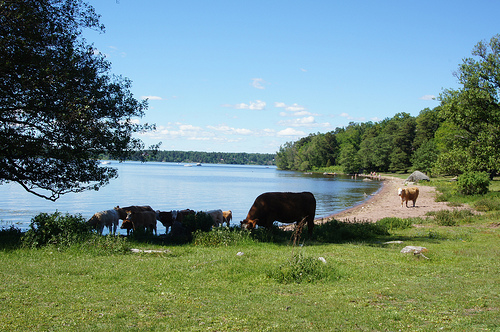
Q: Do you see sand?
A: Yes, there is sand.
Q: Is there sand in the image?
A: Yes, there is sand.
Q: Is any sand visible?
A: Yes, there is sand.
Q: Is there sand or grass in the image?
A: Yes, there is sand.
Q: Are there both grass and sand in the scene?
A: Yes, there are both sand and grass.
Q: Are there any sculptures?
A: No, there are no sculptures.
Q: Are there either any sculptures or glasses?
A: No, there are no sculptures or glasses.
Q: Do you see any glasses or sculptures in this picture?
A: No, there are no sculptures or glasses.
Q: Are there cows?
A: Yes, there is a cow.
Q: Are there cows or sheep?
A: Yes, there is a cow.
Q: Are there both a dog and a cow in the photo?
A: No, there is a cow but no dogs.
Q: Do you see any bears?
A: No, there are no bears.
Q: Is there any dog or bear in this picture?
A: No, there are no bears or dogs.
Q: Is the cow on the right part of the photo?
A: Yes, the cow is on the right of the image.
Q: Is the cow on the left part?
A: No, the cow is on the right of the image.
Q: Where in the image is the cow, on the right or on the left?
A: The cow is on the right of the image.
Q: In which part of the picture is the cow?
A: The cow is on the right of the image.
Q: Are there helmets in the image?
A: No, there are no helmets.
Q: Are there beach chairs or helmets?
A: No, there are no helmets or beach chairs.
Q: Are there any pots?
A: No, there are no pots.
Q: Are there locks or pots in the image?
A: No, there are no pots or locks.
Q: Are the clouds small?
A: Yes, the clouds are small.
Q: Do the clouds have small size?
A: Yes, the clouds are small.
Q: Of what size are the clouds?
A: The clouds are small.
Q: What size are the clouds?
A: The clouds are small.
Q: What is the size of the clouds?
A: The clouds are small.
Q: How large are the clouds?
A: The clouds are small.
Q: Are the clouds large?
A: No, the clouds are small.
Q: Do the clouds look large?
A: No, the clouds are small.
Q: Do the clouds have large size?
A: No, the clouds are small.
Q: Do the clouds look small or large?
A: The clouds are small.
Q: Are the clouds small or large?
A: The clouds are small.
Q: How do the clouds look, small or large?
A: The clouds are small.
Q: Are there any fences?
A: No, there are no fences.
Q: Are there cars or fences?
A: No, there are no fences or cars.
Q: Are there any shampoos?
A: No, there are no shampoos.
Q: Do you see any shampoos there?
A: No, there are no shampoos.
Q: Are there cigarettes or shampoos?
A: No, there are no shampoos or cigarettes.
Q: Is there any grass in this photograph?
A: Yes, there is grass.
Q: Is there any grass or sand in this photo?
A: Yes, there is grass.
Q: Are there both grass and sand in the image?
A: Yes, there are both grass and sand.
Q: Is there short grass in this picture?
A: Yes, there is short grass.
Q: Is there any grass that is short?
A: Yes, there is grass that is short.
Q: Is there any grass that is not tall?
A: Yes, there is short grass.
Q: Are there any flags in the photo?
A: No, there are no flags.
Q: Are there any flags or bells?
A: No, there are no flags or bells.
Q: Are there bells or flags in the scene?
A: No, there are no flags or bells.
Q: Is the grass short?
A: Yes, the grass is short.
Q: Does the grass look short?
A: Yes, the grass is short.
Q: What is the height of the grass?
A: The grass is short.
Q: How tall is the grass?
A: The grass is short.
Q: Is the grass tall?
A: No, the grass is short.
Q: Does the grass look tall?
A: No, the grass is short.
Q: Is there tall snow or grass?
A: No, there is grass but it is short.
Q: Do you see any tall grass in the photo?
A: No, there is grass but it is short.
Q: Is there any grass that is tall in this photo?
A: No, there is grass but it is short.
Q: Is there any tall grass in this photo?
A: No, there is grass but it is short.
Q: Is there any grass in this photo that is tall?
A: No, there is grass but it is short.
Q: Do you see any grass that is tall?
A: No, there is grass but it is short.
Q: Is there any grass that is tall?
A: No, there is grass but it is short.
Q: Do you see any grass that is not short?
A: No, there is grass but it is short.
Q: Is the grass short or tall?
A: The grass is short.